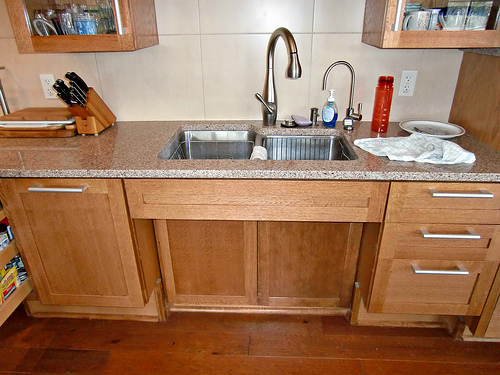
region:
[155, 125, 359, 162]
A silver metal kitchen sink set into the counter top.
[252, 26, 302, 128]
A stainless steel water faucet.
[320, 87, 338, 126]
A plastic bottle filled with blue hand soap.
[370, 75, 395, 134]
A red plastic water bottle.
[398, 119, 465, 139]
A white dinner plate.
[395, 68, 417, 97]
A white electric outlet.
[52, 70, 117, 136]
A rack of kitchen knives.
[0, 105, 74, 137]
A stack of cutting boards.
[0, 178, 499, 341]
The kitchen cupboards have a wood finish.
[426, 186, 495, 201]
The drawer has a stainless steel handle.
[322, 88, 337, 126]
blue hand soap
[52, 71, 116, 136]
a bunch of knives in a block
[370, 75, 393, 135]
orange plastic water bottle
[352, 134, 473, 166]
white towel on the counter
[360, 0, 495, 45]
part of cupboard with cups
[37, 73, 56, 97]
white wall outlet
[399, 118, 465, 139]
plate on the counter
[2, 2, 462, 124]
white tile above the sink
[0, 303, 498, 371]
dark wooden floor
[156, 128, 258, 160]
stainless steel sink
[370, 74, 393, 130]
A bottle used for drinking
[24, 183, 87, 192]
Handle on a cabinet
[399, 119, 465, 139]
A plate on a counter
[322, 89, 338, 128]
A soap container on a counter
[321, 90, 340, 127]
Blue colored soap in a container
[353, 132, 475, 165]
A dish cleaning rag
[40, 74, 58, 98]
A white outlet in a wall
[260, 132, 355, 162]
A metal sink that is empty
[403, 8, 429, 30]
A white mug in a cabinet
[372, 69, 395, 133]
Red bottle on kitchen counter.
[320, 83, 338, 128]
Bottle with hand pump on counter.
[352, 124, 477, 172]
White towel on counter.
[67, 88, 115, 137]
Wooden knife block on counter.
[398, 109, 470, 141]
White plate on counter.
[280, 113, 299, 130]
Metal sink stopper on counter.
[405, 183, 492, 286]
Three metal handles on three kitchen drawers.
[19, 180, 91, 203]
Metal handle of lower kitchen cabinet.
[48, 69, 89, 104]
Knives with black handles in knife block.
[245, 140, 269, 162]
White cloth hanging between the kitchen sinks.